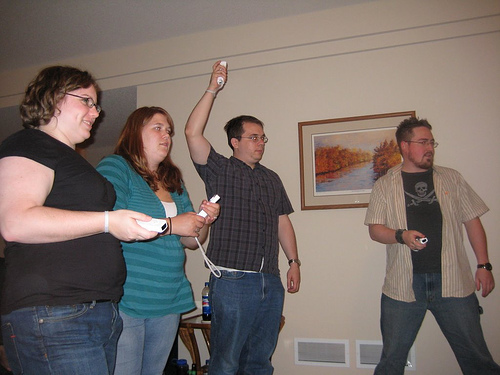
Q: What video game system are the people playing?
A: Wii.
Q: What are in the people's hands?
A: Wii remotes.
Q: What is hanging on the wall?
A: Painting.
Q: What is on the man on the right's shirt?
A: Skull.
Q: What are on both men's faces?
A: Glasses.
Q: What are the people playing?
A: Wii.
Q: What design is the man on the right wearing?
A: Skulls.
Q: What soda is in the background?
A: Pepsi.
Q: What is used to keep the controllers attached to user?
A: A strap.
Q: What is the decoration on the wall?
A: A painting.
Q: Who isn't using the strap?
A: The woman in blue.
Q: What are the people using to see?
A: Glasses.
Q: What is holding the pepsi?
A: A table.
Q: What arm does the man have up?
A: Right.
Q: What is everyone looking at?
A: The television screen.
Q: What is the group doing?
A: Playing video games.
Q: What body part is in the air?
A: Arm.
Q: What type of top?
A: Shirt.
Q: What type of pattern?
A: Stripes.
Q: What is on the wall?
A: Painting.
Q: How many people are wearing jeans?
A: 4.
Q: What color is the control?
A: White.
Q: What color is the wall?
A: Beige.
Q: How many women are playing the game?
A: 2.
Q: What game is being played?
A: Wii.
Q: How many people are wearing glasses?
A: 3.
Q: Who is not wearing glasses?
A: The woman.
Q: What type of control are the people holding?
A: A Wii control.